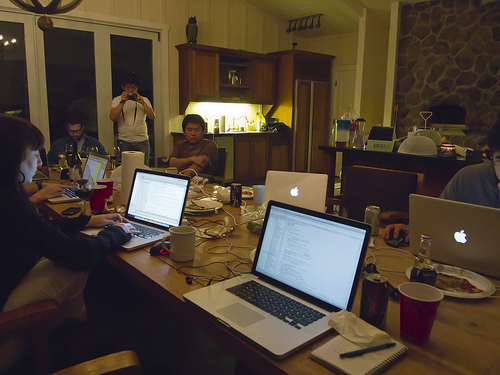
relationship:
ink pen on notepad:
[330, 334, 397, 365] [306, 317, 412, 374]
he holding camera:
[110, 73, 157, 170] [119, 88, 135, 101]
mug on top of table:
[150, 207, 207, 272] [23, 157, 498, 373]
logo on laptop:
[444, 220, 469, 252] [401, 182, 498, 277]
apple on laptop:
[290, 185, 299, 197] [257, 163, 331, 225]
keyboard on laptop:
[231, 279, 324, 331] [184, 201, 374, 358]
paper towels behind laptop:
[116, 149, 153, 173] [98, 170, 189, 249]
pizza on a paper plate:
[433, 272, 484, 294] [403, 263, 497, 299]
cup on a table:
[397, 280, 445, 343] [23, 157, 498, 373]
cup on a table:
[84, 178, 109, 218] [88, 177, 498, 370]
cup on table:
[97, 175, 114, 196] [23, 157, 498, 373]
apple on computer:
[290, 185, 299, 197] [257, 156, 339, 207]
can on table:
[358, 270, 390, 322] [23, 157, 498, 373]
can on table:
[358, 272, 391, 327] [23, 157, 498, 373]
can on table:
[228, 180, 242, 207] [23, 157, 498, 373]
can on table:
[364, 202, 380, 234] [23, 157, 498, 373]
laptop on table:
[76, 169, 193, 256] [23, 157, 498, 373]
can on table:
[358, 272, 391, 327] [68, 147, 462, 370]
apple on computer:
[291, 185, 297, 199] [263, 170, 328, 211]